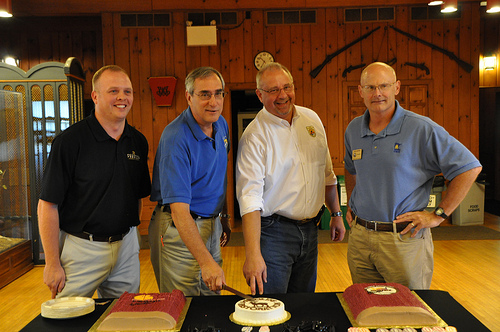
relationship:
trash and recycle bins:
[313, 155, 365, 250] [319, 160, 461, 253]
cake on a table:
[229, 293, 292, 326] [179, 294, 319, 329]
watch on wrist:
[433, 205, 453, 225] [415, 197, 460, 239]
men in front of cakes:
[62, 63, 420, 152] [110, 283, 450, 327]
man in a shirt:
[61, 47, 160, 171] [53, 122, 172, 244]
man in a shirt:
[164, 64, 229, 303] [160, 111, 243, 211]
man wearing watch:
[344, 58, 482, 292] [430, 200, 449, 221]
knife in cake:
[218, 281, 253, 302] [227, 293, 287, 323]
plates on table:
[36, 294, 96, 322] [18, 289, 489, 330]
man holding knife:
[164, 64, 229, 303] [221, 281, 254, 304]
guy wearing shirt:
[235, 62, 345, 295] [232, 102, 339, 222]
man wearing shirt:
[344, 58, 482, 292] [340, 100, 480, 224]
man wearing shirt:
[164, 64, 229, 303] [147, 107, 233, 221]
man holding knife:
[164, 64, 229, 303] [217, 283, 252, 302]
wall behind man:
[81, 0, 479, 230] [344, 58, 482, 292]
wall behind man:
[81, 0, 479, 230] [234, 63, 347, 296]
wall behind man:
[81, 0, 479, 230] [164, 64, 229, 303]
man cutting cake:
[164, 64, 229, 303] [224, 286, 297, 327]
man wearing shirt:
[344, 58, 482, 292] [343, 112, 475, 231]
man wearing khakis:
[344, 58, 482, 292] [349, 210, 438, 290]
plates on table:
[36, 294, 96, 322] [31, 286, 475, 326]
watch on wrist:
[433, 205, 453, 225] [412, 189, 458, 232]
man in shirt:
[164, 64, 229, 303] [156, 106, 234, 219]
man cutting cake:
[164, 64, 229, 303] [222, 291, 300, 325]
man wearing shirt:
[240, 61, 337, 297] [233, 106, 334, 224]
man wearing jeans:
[240, 61, 337, 297] [256, 209, 319, 292]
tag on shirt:
[349, 149, 363, 162] [343, 112, 475, 231]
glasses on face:
[194, 89, 227, 101] [185, 64, 225, 122]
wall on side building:
[81, 0, 479, 230] [0, 0, 497, 329]